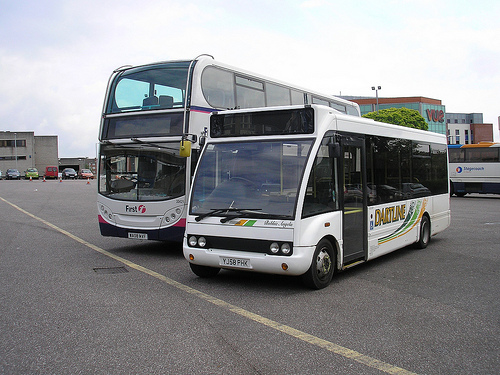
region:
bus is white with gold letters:
[185, 110, 450, 280]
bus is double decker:
[97, 63, 361, 245]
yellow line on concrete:
[1, 193, 418, 373]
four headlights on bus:
[187, 233, 292, 255]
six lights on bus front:
[99, 200, 182, 226]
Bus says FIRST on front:
[122, 203, 148, 214]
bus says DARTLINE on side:
[373, 199, 408, 231]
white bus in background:
[449, 144, 499, 199]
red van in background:
[43, 163, 58, 180]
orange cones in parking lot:
[27, 175, 91, 186]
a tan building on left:
[1, 128, 61, 180]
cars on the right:
[1, 164, 94, 182]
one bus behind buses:
[446, 138, 497, 199]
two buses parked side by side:
[93, 54, 453, 289]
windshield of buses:
[96, 134, 312, 219]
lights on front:
[98, 198, 295, 257]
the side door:
[337, 132, 372, 270]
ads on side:
[369, 196, 431, 244]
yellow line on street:
[1, 193, 407, 373]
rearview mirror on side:
[176, 130, 197, 153]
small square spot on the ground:
[73, 257, 142, 288]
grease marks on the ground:
[190, 295, 240, 317]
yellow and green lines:
[230, 216, 260, 229]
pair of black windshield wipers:
[182, 180, 292, 235]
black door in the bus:
[327, 135, 386, 266]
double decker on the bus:
[117, 52, 313, 114]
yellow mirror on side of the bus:
[168, 134, 200, 160]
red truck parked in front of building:
[37, 162, 59, 179]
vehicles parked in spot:
[11, 162, 99, 185]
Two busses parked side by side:
[67, 36, 479, 290]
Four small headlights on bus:
[188, 228, 292, 260]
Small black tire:
[305, 223, 364, 293]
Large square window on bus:
[189, 123, 321, 230]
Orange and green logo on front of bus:
[230, 211, 261, 231]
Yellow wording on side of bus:
[365, 195, 415, 229]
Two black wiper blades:
[195, 203, 267, 233]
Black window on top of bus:
[201, 98, 328, 146]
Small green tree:
[352, 96, 434, 146]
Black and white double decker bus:
[86, 60, 402, 247]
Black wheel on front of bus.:
[312, 237, 337, 287]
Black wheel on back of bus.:
[409, 195, 454, 262]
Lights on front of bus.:
[182, 229, 310, 276]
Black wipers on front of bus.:
[210, 196, 304, 242]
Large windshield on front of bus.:
[216, 150, 306, 208]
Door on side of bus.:
[327, 145, 376, 282]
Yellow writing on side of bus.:
[365, 205, 421, 225]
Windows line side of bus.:
[365, 145, 445, 202]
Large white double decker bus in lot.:
[122, 68, 187, 260]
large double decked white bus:
[98, 57, 361, 249]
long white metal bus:
[181, 106, 451, 289]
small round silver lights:
[186, 238, 208, 248]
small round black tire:
[308, 239, 337, 288]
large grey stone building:
[1, 132, 58, 177]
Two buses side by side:
[85, 45, 458, 295]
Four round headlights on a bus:
[180, 226, 295, 261]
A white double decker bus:
[86, 47, 366, 252]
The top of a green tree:
[357, 96, 432, 136]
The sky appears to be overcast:
[0, 0, 496, 160]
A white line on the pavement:
[0, 186, 425, 371]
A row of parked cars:
[0, 160, 100, 187]